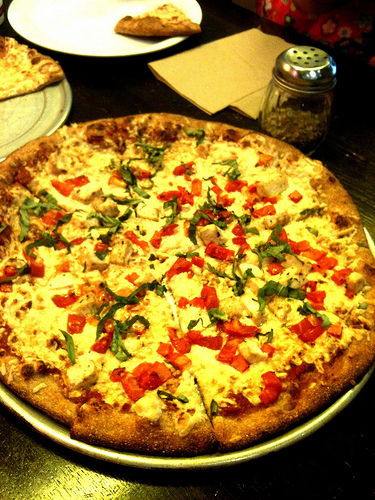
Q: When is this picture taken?
A: During a meal.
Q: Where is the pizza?
A: On the pizza tray.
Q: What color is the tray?
A: Silver.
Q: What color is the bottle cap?
A: Silver.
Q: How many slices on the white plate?
A: One.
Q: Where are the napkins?
A: Between the white plate and the bottle.